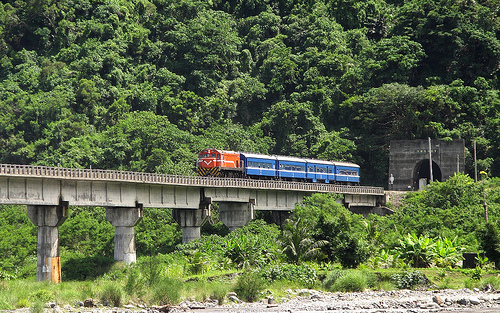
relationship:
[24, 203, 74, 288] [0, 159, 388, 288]
pole under bridge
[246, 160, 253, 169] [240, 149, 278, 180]
window on train car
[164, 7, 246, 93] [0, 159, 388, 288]
tree behind bridge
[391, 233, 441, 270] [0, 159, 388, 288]
bush below bridge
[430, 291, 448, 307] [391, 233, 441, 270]
rock in front of bush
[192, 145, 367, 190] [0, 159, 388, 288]
train on bridge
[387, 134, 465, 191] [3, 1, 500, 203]
tunnel in mountains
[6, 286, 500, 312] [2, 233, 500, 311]
gravel on ground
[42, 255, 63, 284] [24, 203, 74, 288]
door on pole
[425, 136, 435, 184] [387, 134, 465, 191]
pole next to tunnel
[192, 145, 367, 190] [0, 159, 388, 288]
train crossing bridge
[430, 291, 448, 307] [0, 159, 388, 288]
rock under bridge